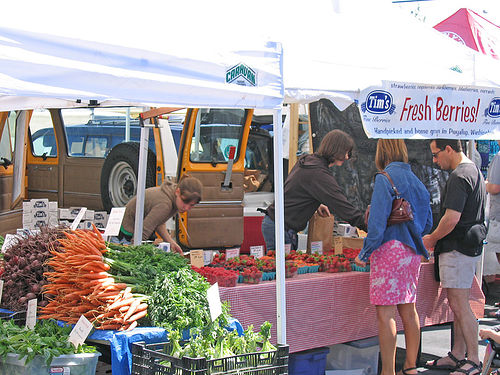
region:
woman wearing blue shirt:
[362, 130, 433, 372]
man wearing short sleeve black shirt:
[423, 138, 499, 373]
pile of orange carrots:
[34, 228, 138, 330]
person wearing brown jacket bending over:
[111, 173, 208, 245]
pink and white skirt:
[367, 244, 429, 312]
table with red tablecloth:
[194, 238, 493, 349]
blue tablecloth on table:
[8, 293, 225, 373]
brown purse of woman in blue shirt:
[360, 170, 411, 227]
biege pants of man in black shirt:
[437, 245, 486, 289]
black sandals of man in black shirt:
[427, 347, 482, 374]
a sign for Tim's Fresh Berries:
[354, 78, 499, 140]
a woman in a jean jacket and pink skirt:
[361, 132, 441, 374]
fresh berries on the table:
[186, 244, 373, 286]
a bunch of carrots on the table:
[35, 223, 220, 333]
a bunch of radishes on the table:
[1, 225, 62, 320]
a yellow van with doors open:
[0, 109, 262, 268]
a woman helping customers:
[260, 120, 374, 260]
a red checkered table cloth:
[206, 263, 490, 360]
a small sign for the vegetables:
[102, 201, 126, 243]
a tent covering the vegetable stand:
[0, 0, 499, 110]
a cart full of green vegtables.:
[112, 288, 287, 373]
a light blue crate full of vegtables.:
[0, 295, 100, 371]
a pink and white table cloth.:
[304, 284, 351, 326]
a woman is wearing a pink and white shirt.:
[378, 245, 415, 294]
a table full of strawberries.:
[179, 237, 368, 287]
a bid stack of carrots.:
[29, 215, 144, 326]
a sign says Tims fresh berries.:
[361, 77, 498, 146]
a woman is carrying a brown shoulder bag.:
[356, 166, 432, 234]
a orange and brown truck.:
[0, 92, 275, 252]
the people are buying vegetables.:
[92, 94, 498, 373]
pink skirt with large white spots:
[368, 239, 424, 306]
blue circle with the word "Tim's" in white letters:
[363, 90, 395, 115]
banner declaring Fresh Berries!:
[358, 86, 498, 138]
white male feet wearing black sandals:
[423, 349, 485, 373]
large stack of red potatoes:
[3, 235, 48, 310]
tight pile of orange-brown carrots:
[35, 227, 139, 318]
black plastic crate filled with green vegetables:
[133, 327, 292, 374]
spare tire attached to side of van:
[100, 145, 153, 213]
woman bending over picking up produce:
[115, 173, 205, 250]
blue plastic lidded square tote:
[288, 344, 330, 373]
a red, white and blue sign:
[357, 76, 498, 140]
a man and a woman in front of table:
[355, 132, 488, 374]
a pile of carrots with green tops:
[37, 222, 231, 332]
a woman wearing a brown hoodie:
[112, 171, 202, 246]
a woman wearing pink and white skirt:
[365, 233, 422, 310]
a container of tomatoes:
[188, 260, 240, 288]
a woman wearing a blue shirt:
[356, 158, 435, 264]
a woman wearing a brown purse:
[366, 168, 415, 231]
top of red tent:
[431, 2, 498, 58]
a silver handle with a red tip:
[220, 143, 236, 188]